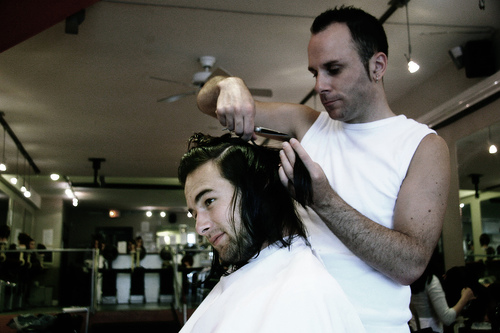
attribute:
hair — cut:
[176, 120, 305, 237]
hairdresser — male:
[190, 1, 451, 331]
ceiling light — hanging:
[401, 3, 421, 73]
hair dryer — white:
[82, 250, 103, 305]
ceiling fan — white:
[152, 42, 272, 106]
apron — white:
[172, 227, 376, 332]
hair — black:
[291, 153, 313, 203]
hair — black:
[172, 126, 309, 273]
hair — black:
[228, 152, 308, 244]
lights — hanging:
[2, 120, 48, 217]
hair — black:
[171, 126, 302, 243]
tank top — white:
[298, 97, 414, 322]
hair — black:
[309, 3, 392, 79]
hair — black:
[171, 124, 317, 261]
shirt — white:
[285, 108, 440, 331]